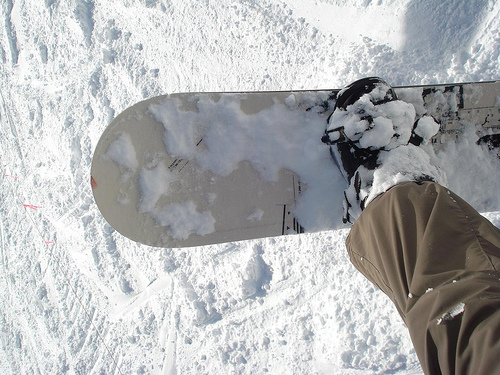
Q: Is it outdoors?
A: Yes, it is outdoors.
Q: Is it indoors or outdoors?
A: It is outdoors.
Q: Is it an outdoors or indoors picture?
A: It is outdoors.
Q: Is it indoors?
A: No, it is outdoors.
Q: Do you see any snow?
A: Yes, there is snow.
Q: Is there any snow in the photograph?
A: Yes, there is snow.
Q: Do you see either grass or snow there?
A: Yes, there is snow.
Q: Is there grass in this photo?
A: No, there is no grass.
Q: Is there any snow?
A: Yes, there is snow.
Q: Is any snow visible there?
A: Yes, there is snow.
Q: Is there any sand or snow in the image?
A: Yes, there is snow.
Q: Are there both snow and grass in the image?
A: No, there is snow but no grass.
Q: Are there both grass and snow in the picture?
A: No, there is snow but no grass.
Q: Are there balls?
A: No, there are no balls.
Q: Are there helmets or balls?
A: No, there are no balls or helmets.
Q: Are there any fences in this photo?
A: No, there are no fences.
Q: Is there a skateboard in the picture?
A: No, there are no skateboards.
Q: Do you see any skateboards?
A: No, there are no skateboards.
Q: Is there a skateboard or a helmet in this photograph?
A: No, there are no skateboards or helmets.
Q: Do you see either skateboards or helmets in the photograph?
A: No, there are no skateboards or helmets.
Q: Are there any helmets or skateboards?
A: No, there are no skateboards or helmets.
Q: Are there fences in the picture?
A: No, there are no fences.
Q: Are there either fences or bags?
A: No, there are no fences or bags.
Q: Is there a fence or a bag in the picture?
A: No, there are no fences or bags.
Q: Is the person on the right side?
A: Yes, the person is on the right of the image.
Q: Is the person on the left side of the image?
A: No, the person is on the right of the image.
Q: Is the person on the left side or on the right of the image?
A: The person is on the right of the image.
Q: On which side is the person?
A: The person is on the right of the image.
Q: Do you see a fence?
A: No, there are no fences.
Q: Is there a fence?
A: No, there are no fences.